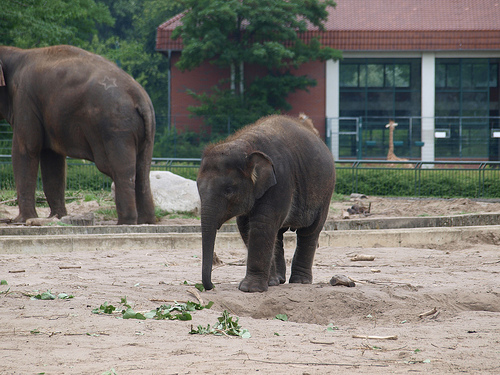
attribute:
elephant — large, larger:
[2, 45, 161, 224]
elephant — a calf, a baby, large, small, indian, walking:
[196, 113, 336, 293]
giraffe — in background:
[385, 121, 414, 168]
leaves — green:
[2, 280, 251, 340]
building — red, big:
[155, 1, 500, 171]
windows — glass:
[338, 53, 500, 163]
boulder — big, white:
[111, 169, 201, 217]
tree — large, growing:
[173, 3, 344, 160]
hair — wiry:
[204, 114, 318, 156]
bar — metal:
[2, 153, 499, 168]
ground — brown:
[2, 240, 495, 371]